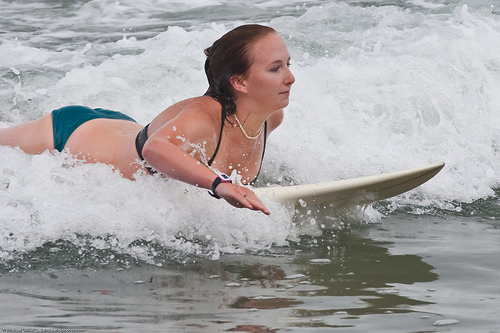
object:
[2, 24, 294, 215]
woman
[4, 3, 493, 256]
waves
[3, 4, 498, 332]
ocean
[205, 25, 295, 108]
head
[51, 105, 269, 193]
bikini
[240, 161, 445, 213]
surfboard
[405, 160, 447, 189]
front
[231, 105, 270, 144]
necklace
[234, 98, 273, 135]
neck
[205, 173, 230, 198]
wrist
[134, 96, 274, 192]
top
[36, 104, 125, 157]
bottoms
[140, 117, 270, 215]
arms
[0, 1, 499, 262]
foam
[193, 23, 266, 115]
hair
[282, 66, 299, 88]
nose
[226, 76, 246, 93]
ear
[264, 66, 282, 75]
eye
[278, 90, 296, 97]
mouth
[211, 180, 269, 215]
hand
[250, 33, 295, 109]
face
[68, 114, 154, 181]
torso